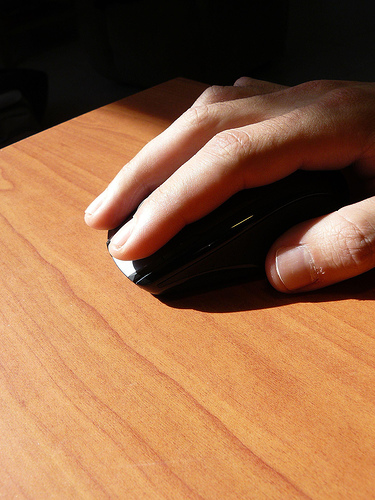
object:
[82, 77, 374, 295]
person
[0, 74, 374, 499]
wood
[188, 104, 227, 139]
knuckles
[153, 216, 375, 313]
shadow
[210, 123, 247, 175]
knuckle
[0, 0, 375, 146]
background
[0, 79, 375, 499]
table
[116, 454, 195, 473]
scratch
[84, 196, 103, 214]
finger nail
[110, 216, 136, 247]
finger nail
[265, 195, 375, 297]
fingers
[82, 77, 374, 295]
hand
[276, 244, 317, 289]
finger nail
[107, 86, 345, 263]
finger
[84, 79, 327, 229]
finger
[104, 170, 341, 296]
computer mouse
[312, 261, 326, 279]
cuticle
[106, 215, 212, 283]
button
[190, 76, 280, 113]
finger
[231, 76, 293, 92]
finger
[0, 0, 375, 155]
dark room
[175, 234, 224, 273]
black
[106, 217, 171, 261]
clickers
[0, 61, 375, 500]
desk